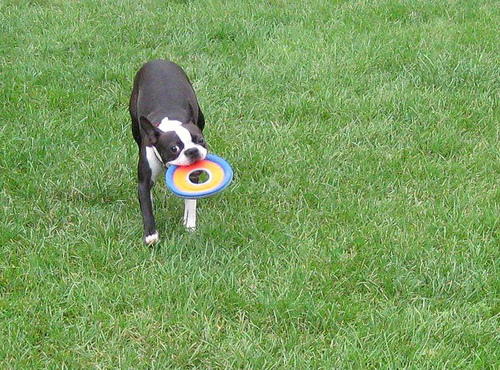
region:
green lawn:
[0, 0, 498, 367]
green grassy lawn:
[0, 0, 498, 368]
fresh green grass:
[0, 2, 498, 367]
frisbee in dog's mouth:
[167, 154, 232, 196]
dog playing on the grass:
[129, 60, 205, 245]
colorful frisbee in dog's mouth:
[165, 152, 231, 194]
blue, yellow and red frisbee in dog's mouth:
[166, 152, 231, 197]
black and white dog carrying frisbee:
[128, 57, 203, 242]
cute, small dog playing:
[128, 58, 203, 244]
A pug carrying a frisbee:
[129, 56, 232, 247]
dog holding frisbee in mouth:
[70, 29, 268, 273]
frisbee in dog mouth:
[170, 160, 232, 199]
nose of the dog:
[185, 145, 212, 161]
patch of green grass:
[260, 323, 302, 367]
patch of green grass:
[429, 250, 471, 290]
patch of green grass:
[299, 242, 329, 279]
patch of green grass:
[57, 229, 104, 279]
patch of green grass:
[356, 194, 382, 233]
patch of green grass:
[302, 130, 337, 160]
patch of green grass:
[43, 163, 87, 216]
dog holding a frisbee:
[125, 58, 232, 244]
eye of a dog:
[170, 143, 179, 153]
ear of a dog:
[138, 115, 163, 145]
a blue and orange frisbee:
[162, 153, 232, 198]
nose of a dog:
[184, 147, 198, 157]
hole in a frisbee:
[188, 168, 211, 184]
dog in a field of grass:
[0, 3, 498, 369]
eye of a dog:
[196, 136, 204, 146]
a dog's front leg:
[136, 147, 168, 248]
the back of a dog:
[128, 58, 195, 121]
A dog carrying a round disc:
[115, 56, 256, 256]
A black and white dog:
[112, 53, 240, 245]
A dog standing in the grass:
[101, 58, 250, 252]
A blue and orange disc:
[152, 145, 239, 205]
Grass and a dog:
[33, 58, 464, 339]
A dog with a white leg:
[179, 196, 201, 237]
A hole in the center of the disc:
[183, 163, 213, 188]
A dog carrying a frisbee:
[117, 63, 248, 260]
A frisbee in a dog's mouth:
[141, 115, 234, 201]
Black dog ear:
[133, 113, 164, 145]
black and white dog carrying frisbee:
[126, 55, 213, 252]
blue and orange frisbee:
[165, 147, 233, 201]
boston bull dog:
[124, 55, 207, 249]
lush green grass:
[251, 43, 433, 333]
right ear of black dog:
[134, 115, 167, 144]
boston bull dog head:
[139, 105, 206, 168]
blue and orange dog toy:
[166, 152, 233, 200]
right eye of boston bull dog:
[168, 143, 180, 153]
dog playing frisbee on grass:
[120, 51, 241, 252]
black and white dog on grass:
[125, 55, 237, 256]